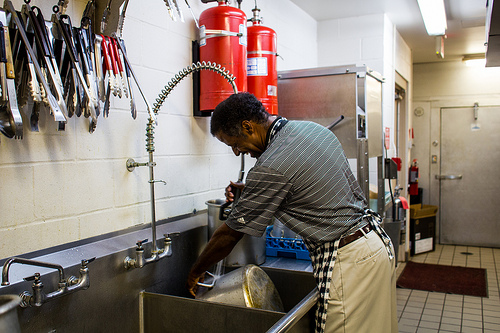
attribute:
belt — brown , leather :
[331, 224, 384, 248]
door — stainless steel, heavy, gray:
[436, 107, 498, 247]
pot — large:
[191, 263, 283, 310]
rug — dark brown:
[398, 258, 489, 300]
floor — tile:
[394, 239, 496, 331]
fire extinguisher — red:
[407, 157, 422, 199]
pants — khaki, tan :
[310, 221, 403, 331]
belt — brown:
[324, 218, 387, 252]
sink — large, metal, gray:
[0, 197, 323, 332]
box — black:
[409, 213, 437, 251]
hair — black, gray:
[210, 91, 271, 138]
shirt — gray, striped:
[224, 118, 374, 247]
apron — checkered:
[265, 113, 408, 331]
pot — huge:
[192, 259, 281, 323]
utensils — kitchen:
[3, 1, 153, 142]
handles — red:
[93, 30, 127, 77]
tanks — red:
[195, 0, 280, 120]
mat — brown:
[388, 249, 490, 303]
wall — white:
[112, 4, 323, 209]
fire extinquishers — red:
[197, 0, 279, 125]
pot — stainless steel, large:
[188, 268, 295, 313]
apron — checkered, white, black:
[307, 244, 333, 332]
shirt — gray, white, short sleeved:
[226, 123, 376, 237]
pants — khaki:
[323, 246, 403, 332]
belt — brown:
[329, 220, 390, 241]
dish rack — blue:
[266, 233, 314, 264]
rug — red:
[399, 251, 489, 302]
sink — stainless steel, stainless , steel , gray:
[18, 210, 315, 330]